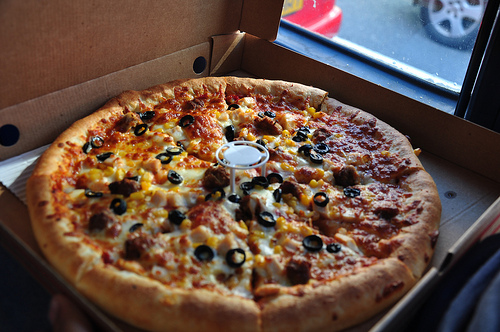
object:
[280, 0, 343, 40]
car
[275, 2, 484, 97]
window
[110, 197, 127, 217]
olives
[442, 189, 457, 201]
spot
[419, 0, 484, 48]
tire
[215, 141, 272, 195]
object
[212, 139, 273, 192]
white stand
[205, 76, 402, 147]
crust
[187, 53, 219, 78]
hole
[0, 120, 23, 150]
hole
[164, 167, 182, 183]
olives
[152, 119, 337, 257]
cheese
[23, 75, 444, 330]
pizza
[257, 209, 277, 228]
olive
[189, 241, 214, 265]
olive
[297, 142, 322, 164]
olive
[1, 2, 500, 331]
box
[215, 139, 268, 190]
topper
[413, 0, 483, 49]
car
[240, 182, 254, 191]
olive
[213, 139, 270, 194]
middle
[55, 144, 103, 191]
sauce